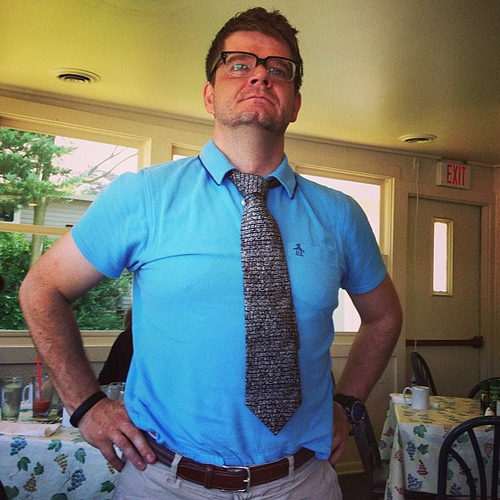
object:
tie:
[222, 170, 304, 435]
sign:
[434, 159, 474, 193]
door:
[403, 192, 484, 401]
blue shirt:
[66, 136, 391, 473]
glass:
[31, 372, 56, 417]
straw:
[33, 352, 44, 400]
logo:
[291, 242, 308, 257]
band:
[66, 389, 110, 431]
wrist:
[58, 377, 110, 427]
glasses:
[207, 49, 302, 84]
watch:
[333, 392, 367, 428]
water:
[1, 385, 22, 419]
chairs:
[432, 412, 500, 499]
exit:
[444, 160, 467, 189]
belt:
[141, 431, 317, 493]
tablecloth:
[377, 391, 500, 499]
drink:
[30, 372, 57, 423]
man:
[17, 4, 404, 499]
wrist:
[329, 377, 372, 431]